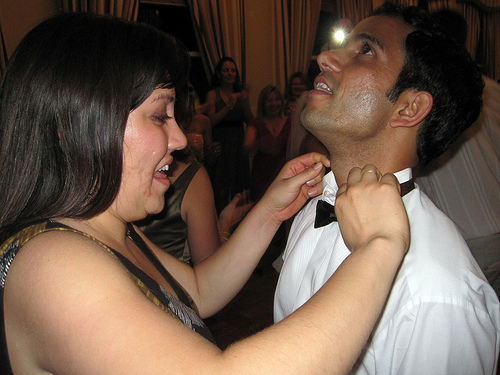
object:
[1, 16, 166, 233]
hair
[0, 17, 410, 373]
woman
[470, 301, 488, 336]
wrinkles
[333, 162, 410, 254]
hand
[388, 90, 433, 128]
ear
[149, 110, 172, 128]
eye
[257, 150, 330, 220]
hand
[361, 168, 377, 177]
ring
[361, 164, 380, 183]
finger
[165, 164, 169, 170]
teeth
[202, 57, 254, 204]
person standing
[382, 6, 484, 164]
hair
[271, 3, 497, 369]
person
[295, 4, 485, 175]
head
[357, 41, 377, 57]
eye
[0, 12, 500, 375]
room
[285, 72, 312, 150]
people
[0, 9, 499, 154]
background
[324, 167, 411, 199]
collar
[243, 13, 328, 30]
air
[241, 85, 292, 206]
partyers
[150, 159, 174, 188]
mouth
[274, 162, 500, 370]
shirt